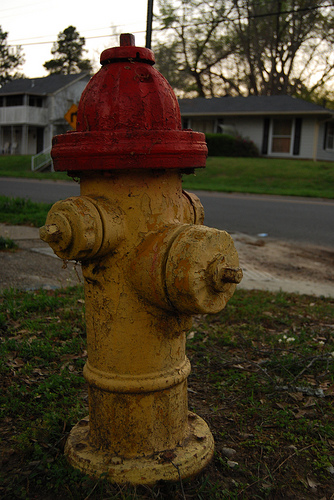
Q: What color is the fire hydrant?
A: Red and yellow.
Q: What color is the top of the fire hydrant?
A: Red.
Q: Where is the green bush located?
A: In front of the one-story house.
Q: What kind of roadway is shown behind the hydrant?
A: Paved road.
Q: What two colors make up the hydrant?
A: Red and yellow.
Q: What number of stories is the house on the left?
A: Two.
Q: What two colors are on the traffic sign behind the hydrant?
A: Orange and black.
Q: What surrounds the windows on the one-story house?
A: Shutters.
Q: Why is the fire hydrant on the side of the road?
A: To put out any fires.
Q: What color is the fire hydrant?
A: Yellow and red.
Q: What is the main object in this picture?
A: Fire hydrant.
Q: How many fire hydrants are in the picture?
A: One.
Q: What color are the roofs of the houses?
A: Black.